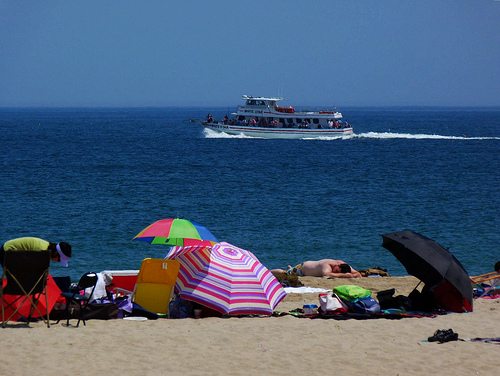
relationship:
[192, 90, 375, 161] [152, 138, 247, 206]
boat in ocean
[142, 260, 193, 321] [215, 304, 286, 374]
chair on beach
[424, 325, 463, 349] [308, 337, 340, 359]
shoes in sand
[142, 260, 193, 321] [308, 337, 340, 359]
chair in sand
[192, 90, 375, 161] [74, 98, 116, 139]
boat in water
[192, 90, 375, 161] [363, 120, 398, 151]
boat makes waves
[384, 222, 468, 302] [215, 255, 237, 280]
umbrella has stripes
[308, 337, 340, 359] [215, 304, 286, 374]
sand on beach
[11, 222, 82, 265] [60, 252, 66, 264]
person wearing cap